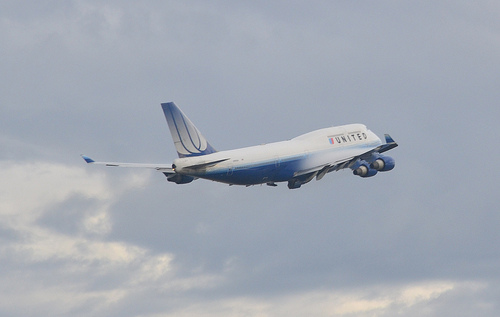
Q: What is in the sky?
A: A plane.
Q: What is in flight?
A: A plane.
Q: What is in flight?
A: A plane.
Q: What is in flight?
A: A plane.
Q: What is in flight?
A: A plane.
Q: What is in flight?
A: A plane.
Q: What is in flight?
A: A plane.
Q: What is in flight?
A: A plane.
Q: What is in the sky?
A: Airplane.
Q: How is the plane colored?
A: White and blue.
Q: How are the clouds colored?
A: Grey.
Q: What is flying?
A: Airplane.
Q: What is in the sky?
A: Airplane.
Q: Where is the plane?
A: Sky.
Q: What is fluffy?
A: Clouds.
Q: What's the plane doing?
A: Flying.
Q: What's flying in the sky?
A: Plane.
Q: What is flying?
A: Airplane.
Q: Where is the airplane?
A: The sky.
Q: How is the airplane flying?
A: Engines.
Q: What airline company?
A: United.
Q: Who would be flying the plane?
A: Pilot.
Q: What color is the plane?
A: Blue and white.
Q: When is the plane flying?
A: Daytime.